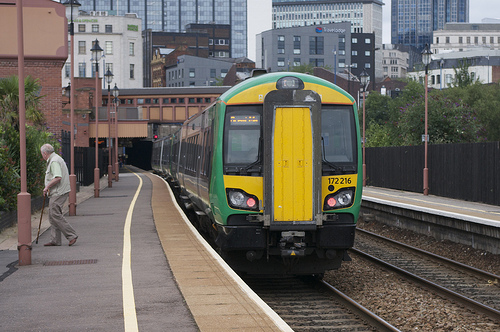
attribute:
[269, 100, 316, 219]
panel — yellow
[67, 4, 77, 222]
pole — metal, tall, red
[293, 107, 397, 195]
window — large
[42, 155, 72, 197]
shirt — white, short sleeved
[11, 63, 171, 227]
lights — painted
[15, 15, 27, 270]
pole — tall, red, metal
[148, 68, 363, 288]
train — green, yellow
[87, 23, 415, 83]
buildings — many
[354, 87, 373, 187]
pole — tall, red, metal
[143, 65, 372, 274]
train — green, yellow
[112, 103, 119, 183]
metal pole — red, tall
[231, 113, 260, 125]
lights — showing